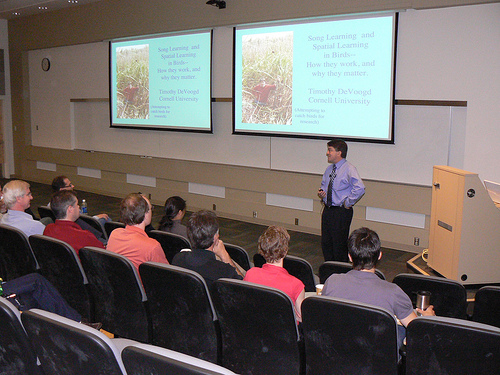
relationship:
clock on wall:
[41, 56, 50, 73] [0, 0, 499, 260]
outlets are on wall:
[148, 194, 419, 246] [0, 0, 499, 260]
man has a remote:
[317, 139, 366, 263] [319, 189, 324, 192]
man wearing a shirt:
[317, 139, 366, 263] [318, 157, 365, 210]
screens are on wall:
[108, 11, 399, 145] [0, 0, 499, 260]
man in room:
[317, 139, 366, 263] [0, 0, 499, 373]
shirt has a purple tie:
[318, 157, 365, 210] [327, 164, 337, 208]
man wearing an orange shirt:
[106, 192, 171, 298] [105, 222, 172, 298]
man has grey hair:
[0, 178, 48, 236] [2, 179, 32, 210]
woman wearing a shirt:
[244, 223, 305, 327] [241, 262, 304, 326]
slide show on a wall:
[108, 11, 399, 145] [0, 0, 499, 260]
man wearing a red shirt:
[41, 189, 106, 264] [41, 219, 106, 261]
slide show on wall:
[108, 11, 399, 145] [0, 0, 499, 260]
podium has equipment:
[425, 164, 499, 285] [483, 180, 498, 205]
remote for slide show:
[319, 189, 324, 192] [108, 11, 399, 145]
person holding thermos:
[319, 227, 436, 364] [414, 291, 432, 315]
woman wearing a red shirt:
[244, 223, 305, 327] [241, 262, 304, 326]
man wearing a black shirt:
[170, 209, 241, 315] [168, 246, 242, 305]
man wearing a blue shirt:
[317, 139, 366, 263] [318, 157, 365, 210]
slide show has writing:
[108, 11, 399, 145] [143, 26, 385, 128]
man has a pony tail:
[157, 194, 193, 240] [158, 206, 174, 231]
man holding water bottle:
[49, 176, 112, 225] [81, 197, 89, 213]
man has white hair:
[0, 178, 48, 236] [2, 179, 32, 210]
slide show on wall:
[108, 11, 399, 145] [41, 15, 483, 190]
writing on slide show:
[298, 32, 380, 132] [108, 11, 399, 145]